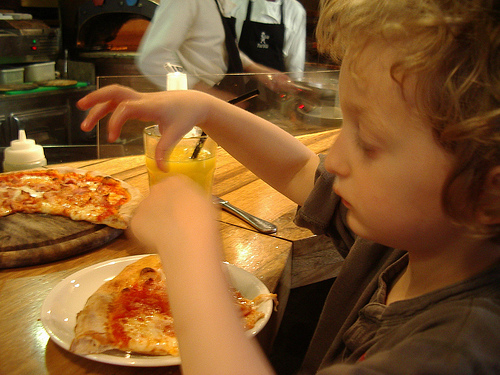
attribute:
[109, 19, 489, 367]
boy — young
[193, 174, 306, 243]
untensil — silver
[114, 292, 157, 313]
sauce — red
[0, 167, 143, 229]
pizza — small, cheese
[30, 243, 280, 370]
plate — white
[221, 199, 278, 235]
handle — heavy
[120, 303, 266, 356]
cheese — white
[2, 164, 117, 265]
board — dark brown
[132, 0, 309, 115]
chef — pizza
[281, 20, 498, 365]
child — brown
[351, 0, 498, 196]
hair — child's, loose curls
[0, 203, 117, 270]
dish — wooden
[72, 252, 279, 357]
pizza — large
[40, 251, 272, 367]
plate — white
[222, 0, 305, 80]
shirt — white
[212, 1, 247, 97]
apron — black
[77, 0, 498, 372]
child — small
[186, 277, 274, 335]
cheese — stringy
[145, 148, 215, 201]
liquid — yellow